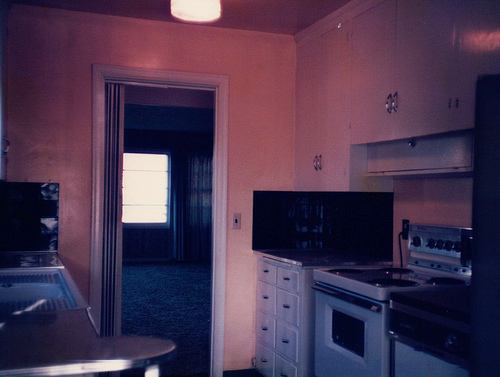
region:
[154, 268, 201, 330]
the ground is carpeted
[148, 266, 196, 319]
the ground is blue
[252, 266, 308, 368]
the drawers are closed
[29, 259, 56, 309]
the sink is mettalic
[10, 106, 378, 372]
the kitchen is clean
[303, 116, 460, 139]
the cabinets are above the stove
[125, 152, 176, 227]
light is coming through the window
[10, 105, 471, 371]
the room is a kitchen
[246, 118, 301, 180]
the walls are pink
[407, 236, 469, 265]
the knobs are black in color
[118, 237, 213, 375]
wall to wall carpeting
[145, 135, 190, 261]
floor length carpeting hangs on the window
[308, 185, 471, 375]
a white electric range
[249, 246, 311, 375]
eight kitchen drawers beneath counter top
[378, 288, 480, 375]
the top of an automatic dishwasher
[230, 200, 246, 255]
The switch for the kitchen lights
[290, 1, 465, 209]
white overhear cupboards with chrome door pulls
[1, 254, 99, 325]
a white, single basin kitchen sink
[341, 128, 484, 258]
an exhaust fan installed over the stove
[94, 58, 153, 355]
an accordion pleated door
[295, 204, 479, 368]
stove under kitchen cabinets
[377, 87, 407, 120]
handles on kitchen cabinets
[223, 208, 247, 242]
switch on kitchen wall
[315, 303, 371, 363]
window on oven door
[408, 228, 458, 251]
knobs on front of stove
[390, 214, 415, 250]
plug in kitchen wall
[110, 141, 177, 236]
sunlight shining through window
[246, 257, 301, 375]
eight drawers on cabinet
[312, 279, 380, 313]
handle on stove door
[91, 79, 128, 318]
folding door in doorway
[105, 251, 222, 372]
Bare carpet floor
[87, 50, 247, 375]
Door jamb with divider looking into living room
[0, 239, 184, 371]
Metal countertop with kitchen sink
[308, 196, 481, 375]
Kitchen oven with electric stove top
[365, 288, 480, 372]
Old dishwasher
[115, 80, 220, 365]
Living room windows with one covered by curtain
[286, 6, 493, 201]
White kitchen cabinets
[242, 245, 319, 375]
White kitchen drawers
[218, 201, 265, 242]
Black light switch with white wall plate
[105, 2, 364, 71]
Circular ceiling light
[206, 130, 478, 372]
A stove in the kitchen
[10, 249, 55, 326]
A sink in the kitchen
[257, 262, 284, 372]
Drawers in the kitchen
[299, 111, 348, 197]
Cupboards in the kitchen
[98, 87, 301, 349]
A sliding door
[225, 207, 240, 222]
A light switch on the wall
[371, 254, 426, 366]
A Stove top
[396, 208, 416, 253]
A power outlet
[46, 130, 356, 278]
A kitchen in the home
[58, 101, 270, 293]
Home kitchen